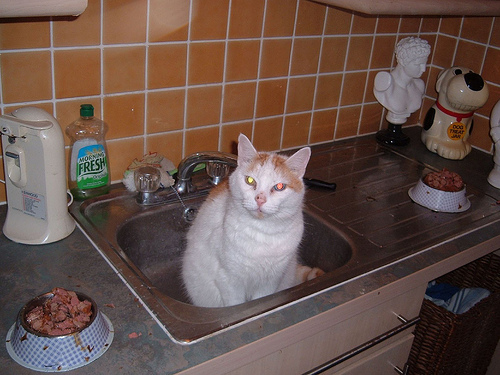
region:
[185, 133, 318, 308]
cat with one yellow eye and one red eye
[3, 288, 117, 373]
cat food in a bowl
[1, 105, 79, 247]
white electric can opener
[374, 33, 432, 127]
white armless statue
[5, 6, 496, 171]
orange tile wall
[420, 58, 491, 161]
dog shaped cookie jar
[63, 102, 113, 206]
meadow fresh dish soap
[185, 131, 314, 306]
white cat with brown spots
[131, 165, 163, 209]
water faucet knob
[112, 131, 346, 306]
white cat sitting in a sink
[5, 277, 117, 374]
an animal food on the bowl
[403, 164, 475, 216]
a bowl of animal food on the counter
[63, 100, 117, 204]
a dishwasher on the sink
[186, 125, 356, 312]
a cat in the sink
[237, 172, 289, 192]
eyes of the cat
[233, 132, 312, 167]
ears of the cat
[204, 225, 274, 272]
a white fur of the cat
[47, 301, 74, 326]
an animal food on the bowl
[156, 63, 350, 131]
a tile backsplash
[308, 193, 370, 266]
a stainless steel sink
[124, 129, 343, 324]
Kitty sitting in the sink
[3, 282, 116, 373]
Bowl of catfood on the counter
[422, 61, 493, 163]
Ceramic dog on the counter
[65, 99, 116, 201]
Bottle of dishsoap behind the sink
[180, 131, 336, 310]
White and orange kitty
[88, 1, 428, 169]
Brown ceramic tiles on the wall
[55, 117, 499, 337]
Stainless steel kitchen sink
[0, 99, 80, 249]
Electric can opener on the counter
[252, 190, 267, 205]
Kitty with a speckled nose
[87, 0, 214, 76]
Reflection in the ceramic tile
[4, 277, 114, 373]
bowl of cat food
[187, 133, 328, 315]
a white and orange cat in the sink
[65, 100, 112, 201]
a soap container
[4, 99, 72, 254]
a white electronic can opener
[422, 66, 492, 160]
cookie jar shaped like a dog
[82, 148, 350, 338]
a silver sink with a cat in it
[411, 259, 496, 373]
basket under the sink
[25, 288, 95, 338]
pile of cat food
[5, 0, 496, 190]
orange tiled wall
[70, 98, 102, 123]
green cap of the soap container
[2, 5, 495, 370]
This is a kitchen scene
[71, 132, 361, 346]
A kitchen sink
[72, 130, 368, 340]
A cat is sitting in the sink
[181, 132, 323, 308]
The cat is orange and white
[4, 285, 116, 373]
A bowl of cat food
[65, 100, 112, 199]
A bottle of dish washing liquid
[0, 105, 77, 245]
An electric can opener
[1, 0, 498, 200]
The wall is tiled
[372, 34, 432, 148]
This is a bust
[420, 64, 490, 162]
A ceramic dog is on the counter